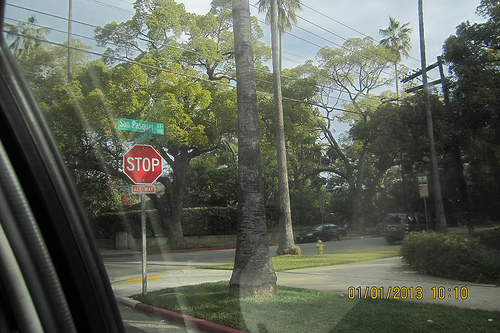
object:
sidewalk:
[275, 256, 500, 311]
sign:
[123, 143, 163, 184]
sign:
[117, 118, 164, 136]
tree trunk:
[227, 0, 277, 299]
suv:
[377, 213, 435, 245]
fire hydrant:
[316, 240, 325, 254]